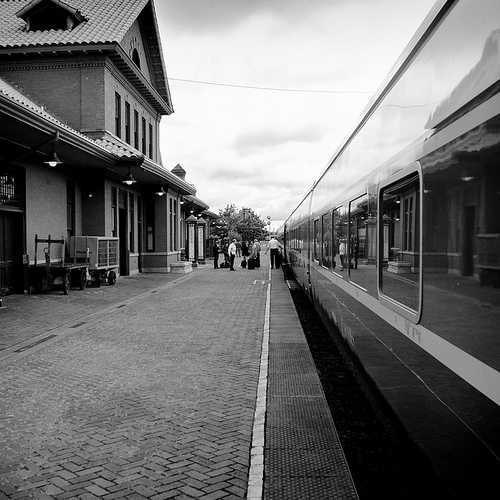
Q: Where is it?
A: This is at the road.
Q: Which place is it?
A: It is a road.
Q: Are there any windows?
A: Yes, there is a window.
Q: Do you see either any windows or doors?
A: Yes, there is a window.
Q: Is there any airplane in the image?
A: Yes, there is an airplane.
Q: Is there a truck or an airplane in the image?
A: Yes, there is an airplane.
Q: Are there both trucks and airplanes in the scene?
A: No, there is an airplane but no trucks.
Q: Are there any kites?
A: No, there are no kites.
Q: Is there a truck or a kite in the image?
A: No, there are no kites or trucks.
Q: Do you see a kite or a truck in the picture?
A: No, there are no kites or trucks.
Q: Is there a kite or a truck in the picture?
A: No, there are no kites or trucks.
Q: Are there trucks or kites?
A: No, there are no kites or trucks.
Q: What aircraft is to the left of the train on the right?
A: The aircraft is an airplane.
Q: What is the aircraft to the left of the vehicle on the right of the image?
A: The aircraft is an airplane.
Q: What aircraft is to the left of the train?
A: The aircraft is an airplane.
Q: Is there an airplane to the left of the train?
A: Yes, there is an airplane to the left of the train.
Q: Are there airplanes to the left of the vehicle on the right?
A: Yes, there is an airplane to the left of the train.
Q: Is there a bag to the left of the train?
A: No, there is an airplane to the left of the train.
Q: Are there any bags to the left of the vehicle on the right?
A: No, there is an airplane to the left of the train.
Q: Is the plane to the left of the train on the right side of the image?
A: Yes, the plane is to the left of the train.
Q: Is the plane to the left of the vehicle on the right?
A: Yes, the plane is to the left of the train.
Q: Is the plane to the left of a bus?
A: No, the plane is to the left of the train.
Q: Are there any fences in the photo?
A: No, there are no fences.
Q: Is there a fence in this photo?
A: No, there are no fences.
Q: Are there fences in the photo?
A: No, there are no fences.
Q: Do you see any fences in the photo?
A: No, there are no fences.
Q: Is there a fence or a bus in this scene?
A: No, there are no fences or buses.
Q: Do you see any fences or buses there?
A: No, there are no fences or buses.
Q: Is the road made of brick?
A: Yes, the road is made of brick.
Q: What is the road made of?
A: The road is made of brick.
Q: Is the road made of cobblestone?
A: No, the road is made of brick.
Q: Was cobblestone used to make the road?
A: No, the road is made of brick.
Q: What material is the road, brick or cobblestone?
A: The road is made of brick.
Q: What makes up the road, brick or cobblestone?
A: The road is made of brick.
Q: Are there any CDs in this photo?
A: No, there are no cds.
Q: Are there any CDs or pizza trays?
A: No, there are no CDs or pizza trays.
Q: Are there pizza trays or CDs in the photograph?
A: No, there are no CDs or pizza trays.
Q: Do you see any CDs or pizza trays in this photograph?
A: No, there are no CDs or pizza trays.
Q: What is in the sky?
A: The clouds are in the sky.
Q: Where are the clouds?
A: The clouds are in the sky.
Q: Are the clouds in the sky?
A: Yes, the clouds are in the sky.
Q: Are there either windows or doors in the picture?
A: Yes, there is a window.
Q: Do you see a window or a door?
A: Yes, there is a window.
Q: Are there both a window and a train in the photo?
A: Yes, there are both a window and a train.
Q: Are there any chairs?
A: No, there are no chairs.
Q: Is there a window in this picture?
A: Yes, there is a window.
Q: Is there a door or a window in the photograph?
A: Yes, there is a window.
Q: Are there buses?
A: No, there are no buses.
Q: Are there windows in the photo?
A: Yes, there are windows.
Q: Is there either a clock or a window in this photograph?
A: Yes, there are windows.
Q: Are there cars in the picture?
A: No, there are no cars.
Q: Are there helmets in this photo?
A: No, there are no helmets.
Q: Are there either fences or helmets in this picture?
A: No, there are no helmets or fences.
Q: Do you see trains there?
A: Yes, there is a train.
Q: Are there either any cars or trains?
A: Yes, there is a train.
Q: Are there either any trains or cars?
A: Yes, there is a train.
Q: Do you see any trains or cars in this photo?
A: Yes, there is a train.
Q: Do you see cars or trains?
A: Yes, there is a train.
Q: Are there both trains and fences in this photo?
A: No, there is a train but no fences.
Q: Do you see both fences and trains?
A: No, there is a train but no fences.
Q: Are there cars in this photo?
A: No, there are no cars.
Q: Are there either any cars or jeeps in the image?
A: No, there are no cars or jeeps.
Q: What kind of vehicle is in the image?
A: The vehicle is a train.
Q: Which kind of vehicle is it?
A: The vehicle is a train.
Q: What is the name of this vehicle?
A: This is a train.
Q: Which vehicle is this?
A: This is a train.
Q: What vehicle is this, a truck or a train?
A: This is a train.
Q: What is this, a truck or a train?
A: This is a train.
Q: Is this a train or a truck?
A: This is a train.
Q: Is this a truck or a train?
A: This is a train.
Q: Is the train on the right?
A: Yes, the train is on the right of the image.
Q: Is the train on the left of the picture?
A: No, the train is on the right of the image.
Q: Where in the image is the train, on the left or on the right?
A: The train is on the right of the image.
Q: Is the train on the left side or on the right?
A: The train is on the right of the image.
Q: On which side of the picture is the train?
A: The train is on the right of the image.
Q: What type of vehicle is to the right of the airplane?
A: The vehicle is a train.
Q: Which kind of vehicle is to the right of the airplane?
A: The vehicle is a train.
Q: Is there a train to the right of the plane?
A: Yes, there is a train to the right of the plane.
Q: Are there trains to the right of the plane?
A: Yes, there is a train to the right of the plane.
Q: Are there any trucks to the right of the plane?
A: No, there is a train to the right of the plane.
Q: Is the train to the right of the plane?
A: Yes, the train is to the right of the plane.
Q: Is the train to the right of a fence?
A: No, the train is to the right of the plane.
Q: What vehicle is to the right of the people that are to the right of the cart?
A: The vehicle is a train.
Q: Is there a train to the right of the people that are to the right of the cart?
A: Yes, there is a train to the right of the people.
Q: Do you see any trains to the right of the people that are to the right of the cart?
A: Yes, there is a train to the right of the people.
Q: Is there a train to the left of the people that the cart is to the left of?
A: No, the train is to the right of the people.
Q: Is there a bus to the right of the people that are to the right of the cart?
A: No, there is a train to the right of the people.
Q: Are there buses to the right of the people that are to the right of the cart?
A: No, there is a train to the right of the people.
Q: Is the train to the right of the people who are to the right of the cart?
A: Yes, the train is to the right of the people.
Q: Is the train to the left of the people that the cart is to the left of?
A: No, the train is to the right of the people.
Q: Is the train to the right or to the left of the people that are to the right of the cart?
A: The train is to the right of the people.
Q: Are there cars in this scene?
A: No, there are no cars.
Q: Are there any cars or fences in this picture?
A: No, there are no cars or fences.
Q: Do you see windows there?
A: Yes, there is a window.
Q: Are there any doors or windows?
A: Yes, there is a window.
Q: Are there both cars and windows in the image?
A: No, there is a window but no cars.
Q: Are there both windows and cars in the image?
A: No, there is a window but no cars.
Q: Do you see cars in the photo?
A: No, there are no cars.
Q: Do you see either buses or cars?
A: No, there are no cars or buses.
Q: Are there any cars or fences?
A: No, there are no cars or fences.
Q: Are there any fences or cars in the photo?
A: No, there are no cars or fences.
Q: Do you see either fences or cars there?
A: No, there are no cars or fences.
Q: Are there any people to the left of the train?
A: Yes, there are people to the left of the train.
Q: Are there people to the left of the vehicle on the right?
A: Yes, there are people to the left of the train.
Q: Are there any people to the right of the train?
A: No, the people are to the left of the train.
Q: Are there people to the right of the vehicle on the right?
A: No, the people are to the left of the train.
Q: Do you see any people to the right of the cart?
A: Yes, there are people to the right of the cart.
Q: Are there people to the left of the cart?
A: No, the people are to the right of the cart.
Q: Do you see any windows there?
A: Yes, there is a window.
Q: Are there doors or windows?
A: Yes, there is a window.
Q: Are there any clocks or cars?
A: No, there are no cars or clocks.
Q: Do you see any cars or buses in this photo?
A: No, there are no cars or buses.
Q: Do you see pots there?
A: No, there are no pots.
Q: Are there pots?
A: No, there are no pots.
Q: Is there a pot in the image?
A: No, there are no pots.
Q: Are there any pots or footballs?
A: No, there are no pots or footballs.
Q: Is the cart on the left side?
A: Yes, the cart is on the left of the image.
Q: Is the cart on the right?
A: No, the cart is on the left of the image.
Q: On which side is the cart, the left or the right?
A: The cart is on the left of the image.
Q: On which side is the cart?
A: The cart is on the left of the image.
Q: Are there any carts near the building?
A: Yes, there is a cart near the building.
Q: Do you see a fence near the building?
A: No, there is a cart near the building.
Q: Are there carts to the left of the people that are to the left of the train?
A: Yes, there is a cart to the left of the people.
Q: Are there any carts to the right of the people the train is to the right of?
A: No, the cart is to the left of the people.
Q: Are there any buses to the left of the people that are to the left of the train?
A: No, there is a cart to the left of the people.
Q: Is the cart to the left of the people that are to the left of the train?
A: Yes, the cart is to the left of the people.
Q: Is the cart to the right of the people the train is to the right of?
A: No, the cart is to the left of the people.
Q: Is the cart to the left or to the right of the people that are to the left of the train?
A: The cart is to the left of the people.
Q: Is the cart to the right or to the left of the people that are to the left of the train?
A: The cart is to the left of the people.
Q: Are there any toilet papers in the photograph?
A: No, there are no toilet papers.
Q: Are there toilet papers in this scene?
A: No, there are no toilet papers.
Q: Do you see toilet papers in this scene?
A: No, there are no toilet papers.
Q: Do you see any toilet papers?
A: No, there are no toilet papers.